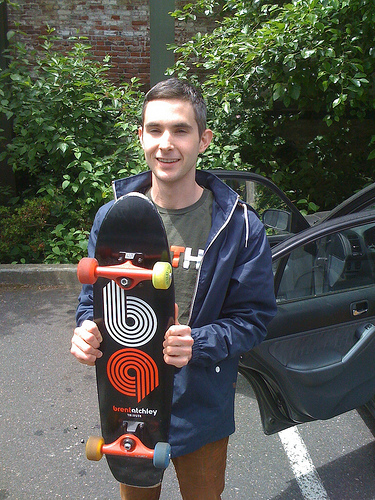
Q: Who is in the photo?
A: A man.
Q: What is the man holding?
A: A skateboard.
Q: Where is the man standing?
A: In a parking lot.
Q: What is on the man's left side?
A: A car.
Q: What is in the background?
A: Trees.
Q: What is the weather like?
A: Sunny.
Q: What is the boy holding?
A: A skateboard.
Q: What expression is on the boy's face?
A: A smile.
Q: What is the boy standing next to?
A: A car.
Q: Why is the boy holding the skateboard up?
A: To display the logo.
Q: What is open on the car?
A: The doors.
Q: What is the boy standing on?
A: Asphalt.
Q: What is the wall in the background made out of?
A: Brick.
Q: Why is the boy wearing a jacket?
A: It's cold outside.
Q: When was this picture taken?
A: Day time.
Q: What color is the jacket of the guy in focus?
A: Blue.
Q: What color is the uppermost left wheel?
A: Red.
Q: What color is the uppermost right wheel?
A: Yellow.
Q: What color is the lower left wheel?
A: Orange.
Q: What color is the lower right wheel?
A: Blue.